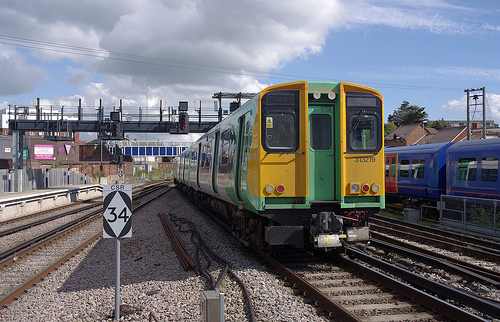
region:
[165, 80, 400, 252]
this is a train on the tracks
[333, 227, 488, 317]
some of the train tracks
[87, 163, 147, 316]
a sign for the rail yard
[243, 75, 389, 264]
the train is green and yellow in color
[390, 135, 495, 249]
this train is red and blue in color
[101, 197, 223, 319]
there is gravel in between the tracks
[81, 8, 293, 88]
a large cloud in the sky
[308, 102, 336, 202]
the door for the train car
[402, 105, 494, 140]
these are roofs to nearby homes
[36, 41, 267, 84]
these are power lines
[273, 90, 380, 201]
front of passenger train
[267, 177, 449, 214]
train is yellow and green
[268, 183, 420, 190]
lights on passenger train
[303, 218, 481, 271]
black tracks near train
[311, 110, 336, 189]
train has green door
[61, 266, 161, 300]
pebbles near train tracks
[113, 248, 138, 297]
metal pole holding sign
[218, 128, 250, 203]
window of passenger train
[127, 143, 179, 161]
white building in distance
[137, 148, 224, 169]
building with blue windows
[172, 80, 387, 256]
a light green and yellow train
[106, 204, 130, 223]
the number 34 in black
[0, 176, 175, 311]
a pair of brown railroad tracks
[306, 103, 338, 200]
a slim small green train door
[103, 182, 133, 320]
a white and black train sign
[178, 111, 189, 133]
a black red light train traffic light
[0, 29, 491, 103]
some power lines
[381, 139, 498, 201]
a blue and red train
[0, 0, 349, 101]
some white patchy white clouds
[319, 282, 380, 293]
a wooden train track slat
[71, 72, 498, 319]
trains on railroad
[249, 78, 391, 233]
front of train is yellow and green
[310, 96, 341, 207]
a green door in front of train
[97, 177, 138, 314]
a sign on side railroad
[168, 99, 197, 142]
a traffic light on a bridge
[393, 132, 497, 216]
a blue train on railroad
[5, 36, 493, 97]
power lines pass over a train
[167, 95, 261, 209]
side of train color green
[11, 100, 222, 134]
a bridge over a train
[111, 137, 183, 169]
bridges on the background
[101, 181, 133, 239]
Black and white sign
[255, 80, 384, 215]
Green and yellow train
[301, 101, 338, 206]
Green door at end of train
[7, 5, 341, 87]
Large white puffy clouds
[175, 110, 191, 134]
Traffic light on red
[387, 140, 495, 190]
Blue and red train in background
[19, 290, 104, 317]
Gray loose gravel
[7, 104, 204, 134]
Black steel overpass above train track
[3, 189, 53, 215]
White concrete platform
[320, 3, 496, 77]
Bright blue sky